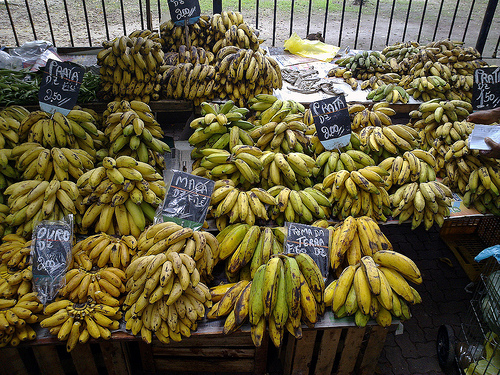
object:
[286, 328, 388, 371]
crates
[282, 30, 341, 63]
bag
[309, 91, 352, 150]
numbers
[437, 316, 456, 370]
wheel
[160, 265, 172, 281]
spot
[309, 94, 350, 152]
sign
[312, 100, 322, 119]
letter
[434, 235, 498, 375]
cart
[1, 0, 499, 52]
gate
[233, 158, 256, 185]
banana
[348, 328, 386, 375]
crate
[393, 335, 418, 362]
bricks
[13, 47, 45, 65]
bag